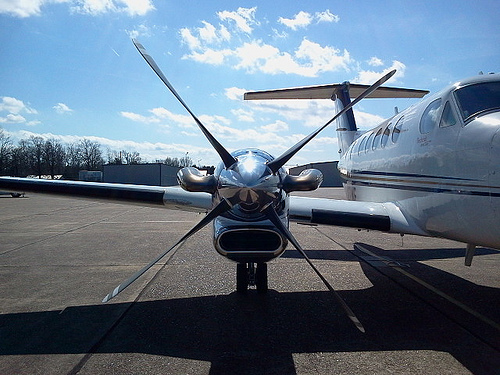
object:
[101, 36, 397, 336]
propeller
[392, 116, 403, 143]
window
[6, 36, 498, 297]
airplane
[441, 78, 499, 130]
windshield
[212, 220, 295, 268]
engine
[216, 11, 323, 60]
clouds